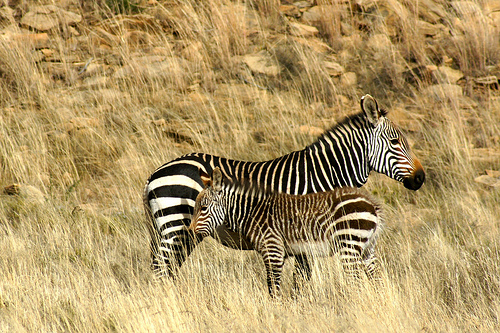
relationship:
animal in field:
[188, 165, 386, 304] [20, 17, 313, 164]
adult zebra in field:
[142, 92, 425, 285] [20, 17, 313, 164]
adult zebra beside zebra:
[142, 92, 425, 285] [121, 83, 433, 220]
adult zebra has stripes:
[142, 92, 425, 285] [148, 150, 211, 282]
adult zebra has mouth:
[142, 92, 425, 285] [402, 169, 425, 191]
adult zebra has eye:
[142, 92, 425, 285] [389, 135, 401, 146]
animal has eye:
[188, 165, 386, 304] [199, 200, 205, 212]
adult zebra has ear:
[142, 92, 425, 285] [350, 93, 390, 130]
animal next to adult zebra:
[188, 165, 386, 304] [103, 89, 439, 244]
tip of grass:
[373, 281, 379, 287] [2, 1, 497, 328]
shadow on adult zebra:
[170, 194, 192, 234] [142, 92, 425, 285]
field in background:
[0, 0, 499, 333] [0, 0, 500, 149]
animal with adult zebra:
[188, 165, 386, 304] [142, 92, 425, 285]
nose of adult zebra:
[417, 169, 426, 180] [142, 92, 425, 285]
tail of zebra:
[141, 176, 159, 259] [124, 97, 424, 271]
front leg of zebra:
[257, 239, 288, 302] [181, 171, 384, 301]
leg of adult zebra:
[149, 158, 213, 282] [142, 92, 425, 285]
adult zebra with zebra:
[142, 92, 425, 285] [181, 171, 384, 301]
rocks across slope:
[2, 3, 499, 128] [5, 3, 484, 216]